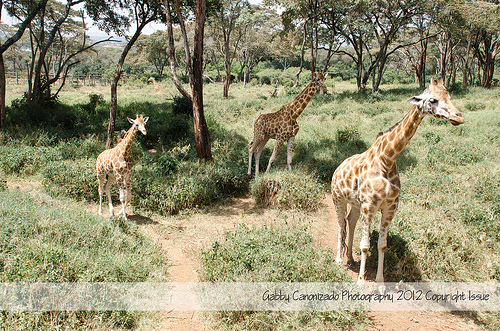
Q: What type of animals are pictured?
A: Giraffe.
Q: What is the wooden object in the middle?
A: A tree.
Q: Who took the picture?
A: Gabby Canonizado.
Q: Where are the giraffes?
A: Near a grove of trees.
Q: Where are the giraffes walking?
A: In the trails.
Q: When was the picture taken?
A: 2012.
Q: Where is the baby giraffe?
A: Following the adult giraffe.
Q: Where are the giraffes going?
A: To the water hole.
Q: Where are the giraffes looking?
A: Forward.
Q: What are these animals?
A: Giraffes.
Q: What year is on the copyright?
A: 2012.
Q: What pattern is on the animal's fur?
A: Spots.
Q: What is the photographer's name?
A: Gabby Caronzado.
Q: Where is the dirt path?
A: In the grass.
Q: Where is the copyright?
A: On the bottom of the picture.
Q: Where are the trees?
A: Behind the animals.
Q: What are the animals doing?
A: Walking.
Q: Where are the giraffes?
A: On a dirt path.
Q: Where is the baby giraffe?
A: To the left.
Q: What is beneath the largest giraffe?
A: Dirt.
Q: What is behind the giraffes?
A: Trees.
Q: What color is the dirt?
A: Brown.